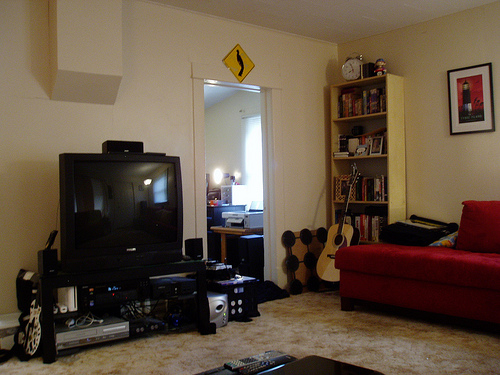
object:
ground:
[182, 327, 343, 364]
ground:
[172, 327, 378, 373]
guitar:
[316, 161, 367, 281]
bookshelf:
[329, 73, 406, 244]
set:
[53, 320, 131, 350]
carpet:
[0, 288, 500, 372]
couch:
[334, 201, 499, 331]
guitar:
[316, 168, 359, 282]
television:
[59, 154, 183, 274]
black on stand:
[41, 263, 216, 361]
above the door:
[203, 80, 275, 281]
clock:
[341, 52, 363, 80]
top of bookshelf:
[327, 54, 390, 87]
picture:
[448, 63, 496, 136]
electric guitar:
[16, 237, 59, 362]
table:
[210, 226, 263, 262]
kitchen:
[202, 81, 264, 277]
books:
[334, 87, 384, 244]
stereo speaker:
[208, 291, 230, 327]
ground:
[3, 309, 500, 373]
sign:
[222, 43, 255, 83]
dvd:
[55, 319, 129, 350]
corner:
[269, 29, 403, 296]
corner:
[0, 1, 497, 106]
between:
[191, 61, 275, 280]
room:
[0, 2, 500, 375]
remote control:
[222, 347, 296, 374]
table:
[188, 348, 385, 374]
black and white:
[14, 267, 43, 358]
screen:
[72, 162, 175, 239]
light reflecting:
[144, 178, 152, 185]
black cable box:
[83, 283, 142, 305]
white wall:
[0, 2, 491, 313]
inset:
[50, 0, 124, 104]